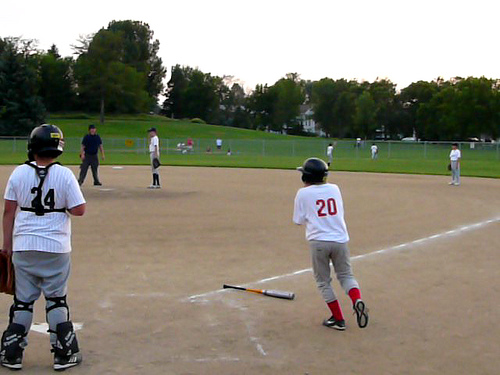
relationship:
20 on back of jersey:
[308, 199, 385, 226] [291, 182, 352, 245]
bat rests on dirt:
[211, 273, 314, 331] [159, 179, 229, 256]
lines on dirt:
[87, 215, 491, 372] [2, 175, 497, 373]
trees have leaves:
[0, 18, 500, 139] [1, 19, 499, 147]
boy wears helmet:
[0, 122, 85, 371] [18, 126, 61, 149]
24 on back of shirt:
[28, 179, 58, 208] [13, 170, 81, 256]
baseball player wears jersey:
[288, 158, 373, 333] [291, 182, 352, 245]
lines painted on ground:
[191, 216, 493, 295] [0, 165, 500, 373]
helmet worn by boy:
[26, 122, 65, 158] [0, 122, 85, 371]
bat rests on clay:
[217, 281, 297, 301] [1, 134, 493, 373]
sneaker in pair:
[316, 316, 346, 332] [319, 297, 369, 329]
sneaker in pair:
[356, 298, 369, 328] [319, 297, 369, 329]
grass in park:
[0, 98, 498, 175] [6, 108, 484, 168]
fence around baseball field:
[1, 132, 498, 167] [3, 140, 496, 372]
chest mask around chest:
[11, 160, 74, 220] [12, 160, 74, 257]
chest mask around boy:
[11, 160, 74, 220] [3, 114, 89, 364]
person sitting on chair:
[183, 137, 193, 152] [190, 140, 194, 151]